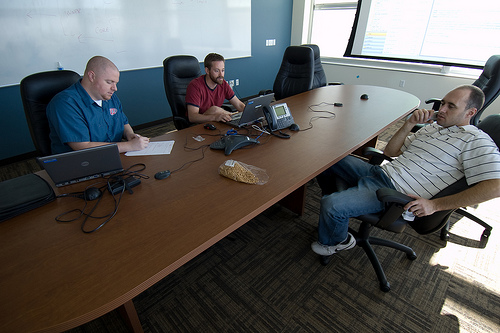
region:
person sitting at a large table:
[43, 52, 150, 157]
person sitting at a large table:
[185, 47, 248, 124]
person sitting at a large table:
[306, 81, 498, 258]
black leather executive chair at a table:
[15, 65, 85, 166]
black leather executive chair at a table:
[158, 52, 205, 129]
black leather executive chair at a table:
[268, 43, 316, 100]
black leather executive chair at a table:
[295, 40, 328, 91]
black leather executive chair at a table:
[422, 53, 499, 121]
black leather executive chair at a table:
[333, 111, 498, 293]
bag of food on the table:
[213, 153, 273, 193]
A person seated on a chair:
[322, 71, 487, 268]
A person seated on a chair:
[160, 34, 240, 119]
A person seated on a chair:
[30, 61, 149, 136]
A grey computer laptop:
[40, 155, 132, 180]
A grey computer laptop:
[229, 95, 270, 127]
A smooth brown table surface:
[12, 234, 120, 296]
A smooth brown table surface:
[122, 209, 212, 244]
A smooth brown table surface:
[261, 150, 318, 178]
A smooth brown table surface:
[308, 81, 395, 120]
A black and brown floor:
[230, 284, 415, 331]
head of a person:
[200, 52, 234, 85]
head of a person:
[79, 53, 125, 110]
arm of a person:
[74, 110, 121, 160]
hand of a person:
[128, 135, 148, 152]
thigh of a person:
[337, 180, 385, 205]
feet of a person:
[303, 233, 352, 259]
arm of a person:
[436, 168, 487, 217]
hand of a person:
[389, 180, 454, 229]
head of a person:
[427, 73, 481, 136]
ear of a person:
[465, 99, 482, 119]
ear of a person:
[466, 106, 476, 116]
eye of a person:
[436, 100, 468, 110]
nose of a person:
[434, 106, 448, 116]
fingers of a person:
[413, 106, 431, 120]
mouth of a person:
[433, 110, 445, 127]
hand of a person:
[393, 197, 438, 225]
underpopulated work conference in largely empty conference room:
[2, 0, 498, 331]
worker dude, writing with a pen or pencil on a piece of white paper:
[40, 53, 175, 162]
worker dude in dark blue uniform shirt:
[42, 78, 149, 155]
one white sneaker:
[297, 226, 360, 262]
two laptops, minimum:
[25, 82, 298, 247]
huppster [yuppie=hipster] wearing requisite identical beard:
[175, 46, 251, 129]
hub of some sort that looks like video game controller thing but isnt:
[199, 126, 273, 161]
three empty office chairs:
[263, 31, 499, 131]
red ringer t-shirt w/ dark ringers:
[184, 72, 241, 114]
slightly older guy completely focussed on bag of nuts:
[212, 91, 484, 193]